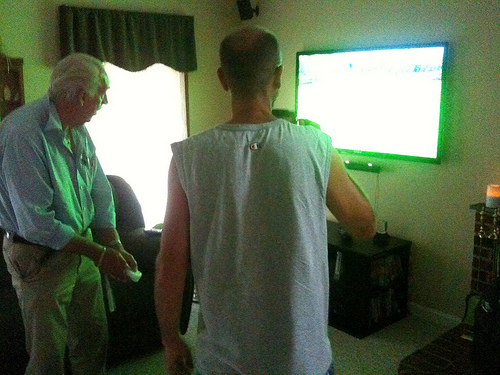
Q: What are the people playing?
A: Wii.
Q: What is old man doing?
A: Playing wii.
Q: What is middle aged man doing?
A: Watching the wii game.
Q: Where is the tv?
A: Mounted on the wall.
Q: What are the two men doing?
A: Watching and playing wii game.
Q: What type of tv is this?
A: Flat screen tv.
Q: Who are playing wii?
A: Two men.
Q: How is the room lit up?
A: Light from window and tv.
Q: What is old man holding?
A: Wii remote.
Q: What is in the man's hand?
A: Wii remote.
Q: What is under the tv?
A: Entertainment center.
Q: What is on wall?
A: Television.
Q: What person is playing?
A: Older man.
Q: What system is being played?
A: Wii.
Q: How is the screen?
A: Bright.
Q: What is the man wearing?
A: Trousers.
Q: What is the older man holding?
A: A game controller.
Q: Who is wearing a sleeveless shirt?
A: The man on the right.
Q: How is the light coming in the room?
A: Through the window.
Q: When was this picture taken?
A: During the daytime.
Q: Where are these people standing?
A: Inside.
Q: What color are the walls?
A: Tan.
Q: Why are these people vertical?
A: Standing up.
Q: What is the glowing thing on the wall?
A: A television.